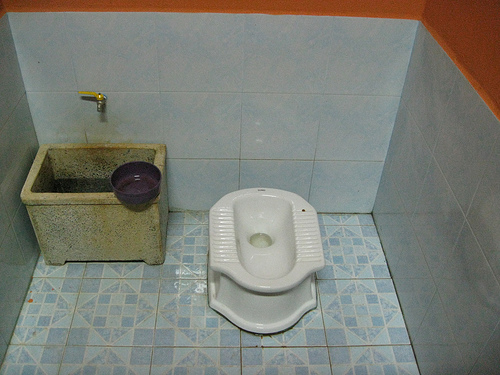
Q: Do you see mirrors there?
A: No, there are no mirrors.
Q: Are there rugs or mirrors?
A: No, there are no mirrors or rugs.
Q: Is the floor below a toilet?
A: Yes, the floor is below a toilet.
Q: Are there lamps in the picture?
A: No, there are no lamps.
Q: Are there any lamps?
A: No, there are no lamps.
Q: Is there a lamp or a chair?
A: No, there are no lamps or chairs.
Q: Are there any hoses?
A: No, there are no hoses.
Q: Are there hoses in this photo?
A: No, there are no hoses.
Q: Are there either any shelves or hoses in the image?
A: No, there are no hoses or shelves.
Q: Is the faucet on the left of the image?
A: Yes, the faucet is on the left of the image.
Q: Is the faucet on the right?
A: No, the faucet is on the left of the image.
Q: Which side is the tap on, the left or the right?
A: The tap is on the left of the image.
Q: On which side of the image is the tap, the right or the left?
A: The tap is on the left of the image.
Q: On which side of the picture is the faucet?
A: The faucet is on the left of the image.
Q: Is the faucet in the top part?
A: Yes, the faucet is in the top of the image.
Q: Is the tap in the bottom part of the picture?
A: No, the tap is in the top of the image.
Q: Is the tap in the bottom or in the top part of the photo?
A: The tap is in the top of the image.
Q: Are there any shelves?
A: No, there are no shelves.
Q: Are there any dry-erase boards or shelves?
A: No, there are no shelves or dry-erase boards.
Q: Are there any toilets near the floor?
A: Yes, there is a toilet near the floor.